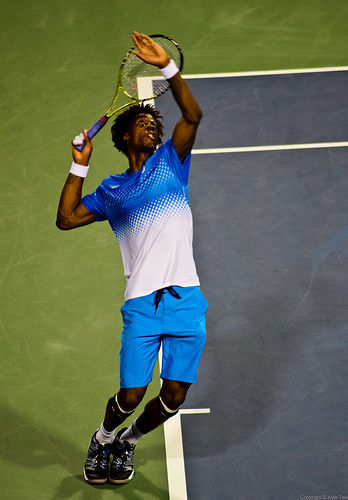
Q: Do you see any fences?
A: No, there are no fences.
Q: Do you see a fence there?
A: No, there are no fences.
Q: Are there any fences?
A: No, there are no fences.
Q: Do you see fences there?
A: No, there are no fences.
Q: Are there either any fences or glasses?
A: No, there are no fences or glasses.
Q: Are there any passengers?
A: No, there are no passengers.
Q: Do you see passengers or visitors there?
A: No, there are no passengers or visitors.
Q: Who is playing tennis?
A: The man is playing tennis.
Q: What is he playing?
A: The man is playing tennis.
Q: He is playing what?
A: The man is playing tennis.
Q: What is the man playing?
A: The man is playing tennis.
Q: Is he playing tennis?
A: Yes, the man is playing tennis.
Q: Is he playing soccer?
A: No, the man is playing tennis.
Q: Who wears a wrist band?
A: The man wears a wrist band.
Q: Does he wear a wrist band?
A: Yes, the man wears a wrist band.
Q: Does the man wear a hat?
A: No, the man wears a wrist band.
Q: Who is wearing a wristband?
A: The man is wearing a wristband.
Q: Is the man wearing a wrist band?
A: Yes, the man is wearing a wrist band.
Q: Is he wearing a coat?
A: No, the man is wearing a wrist band.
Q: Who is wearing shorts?
A: The man is wearing shorts.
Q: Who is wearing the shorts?
A: The man is wearing shorts.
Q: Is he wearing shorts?
A: Yes, the man is wearing shorts.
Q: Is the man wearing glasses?
A: No, the man is wearing shorts.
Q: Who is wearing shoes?
A: The man is wearing shoes.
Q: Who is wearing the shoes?
A: The man is wearing shoes.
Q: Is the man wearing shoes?
A: Yes, the man is wearing shoes.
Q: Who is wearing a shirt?
A: The man is wearing a shirt.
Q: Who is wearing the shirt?
A: The man is wearing a shirt.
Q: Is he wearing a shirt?
A: Yes, the man is wearing a shirt.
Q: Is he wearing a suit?
A: No, the man is wearing a shirt.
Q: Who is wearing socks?
A: The man is wearing socks.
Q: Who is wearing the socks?
A: The man is wearing socks.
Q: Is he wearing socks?
A: Yes, the man is wearing socks.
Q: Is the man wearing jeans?
A: No, the man is wearing socks.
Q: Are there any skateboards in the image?
A: No, there are no skateboards.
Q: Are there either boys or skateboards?
A: No, there are no skateboards or boys.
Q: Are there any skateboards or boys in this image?
A: No, there are no skateboards or boys.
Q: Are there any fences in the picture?
A: No, there are no fences.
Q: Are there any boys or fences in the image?
A: No, there are no fences or boys.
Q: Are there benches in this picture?
A: No, there are no benches.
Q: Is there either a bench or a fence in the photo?
A: No, there are no benches or fences.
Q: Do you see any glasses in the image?
A: No, there are no glasses.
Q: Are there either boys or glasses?
A: No, there are no glasses or boys.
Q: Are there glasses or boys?
A: No, there are no glasses or boys.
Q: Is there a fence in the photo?
A: No, there are no fences.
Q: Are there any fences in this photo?
A: No, there are no fences.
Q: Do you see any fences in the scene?
A: No, there are no fences.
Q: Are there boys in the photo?
A: No, there are no boys.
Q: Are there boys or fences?
A: No, there are no boys or fences.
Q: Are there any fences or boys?
A: No, there are no boys or fences.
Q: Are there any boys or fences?
A: No, there are no fences or boys.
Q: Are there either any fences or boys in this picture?
A: No, there are no fences or boys.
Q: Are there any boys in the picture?
A: No, there are no boys.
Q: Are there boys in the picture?
A: No, there are no boys.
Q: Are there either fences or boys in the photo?
A: No, there are no boys or fences.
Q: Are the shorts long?
A: Yes, the shorts are long.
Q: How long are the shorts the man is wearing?
A: The shorts are long.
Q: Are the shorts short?
A: No, the shorts are long.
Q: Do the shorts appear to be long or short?
A: The shorts are long.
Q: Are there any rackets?
A: Yes, there is a racket.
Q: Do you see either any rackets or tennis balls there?
A: Yes, there is a racket.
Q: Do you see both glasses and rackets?
A: No, there is a racket but no glasses.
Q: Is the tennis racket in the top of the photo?
A: Yes, the tennis racket is in the top of the image.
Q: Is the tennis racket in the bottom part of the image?
A: No, the tennis racket is in the top of the image.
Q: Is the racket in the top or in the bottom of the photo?
A: The racket is in the top of the image.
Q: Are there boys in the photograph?
A: No, there are no boys.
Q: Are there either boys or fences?
A: No, there are no boys or fences.